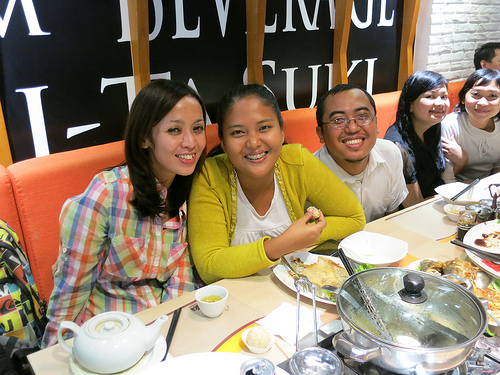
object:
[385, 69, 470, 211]
woman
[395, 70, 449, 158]
hair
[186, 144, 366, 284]
sweater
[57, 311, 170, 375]
tea kettle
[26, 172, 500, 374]
table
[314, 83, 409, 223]
man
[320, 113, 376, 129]
glasses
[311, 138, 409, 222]
shirt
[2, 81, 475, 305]
seating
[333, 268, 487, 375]
pot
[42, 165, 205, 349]
shirt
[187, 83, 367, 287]
young woman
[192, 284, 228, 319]
cup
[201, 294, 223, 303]
soup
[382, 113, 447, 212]
shirt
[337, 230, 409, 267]
plate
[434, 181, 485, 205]
bowl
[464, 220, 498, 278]
serving dish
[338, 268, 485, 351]
lid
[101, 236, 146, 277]
pocket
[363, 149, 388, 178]
part of collar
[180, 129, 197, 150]
nose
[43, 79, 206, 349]
young woman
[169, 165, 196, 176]
chin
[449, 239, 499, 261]
tongs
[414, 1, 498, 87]
wall